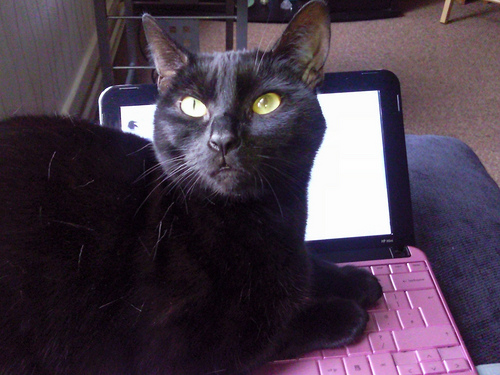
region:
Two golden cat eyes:
[181, 89, 281, 120]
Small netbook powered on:
[92, 68, 473, 374]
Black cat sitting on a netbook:
[0, 1, 382, 373]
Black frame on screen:
[95, 71, 418, 261]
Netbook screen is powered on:
[120, 90, 394, 237]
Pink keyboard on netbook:
[274, 246, 479, 373]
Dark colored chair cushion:
[401, 133, 498, 365]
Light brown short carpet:
[101, 1, 497, 186]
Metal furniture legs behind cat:
[92, 0, 249, 87]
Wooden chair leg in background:
[437, 0, 454, 25]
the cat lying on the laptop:
[1, 0, 383, 372]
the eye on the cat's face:
[251, 90, 281, 112]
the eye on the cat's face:
[178, 95, 208, 117]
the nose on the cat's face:
[209, 133, 236, 154]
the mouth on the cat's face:
[207, 153, 244, 176]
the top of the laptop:
[96, 67, 412, 243]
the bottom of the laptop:
[215, 243, 477, 373]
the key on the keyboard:
[391, 325, 459, 350]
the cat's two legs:
[267, 253, 382, 353]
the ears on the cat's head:
[142, 0, 331, 93]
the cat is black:
[47, 20, 364, 374]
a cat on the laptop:
[44, 42, 421, 370]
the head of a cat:
[176, 2, 336, 189]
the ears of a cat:
[135, 7, 352, 104]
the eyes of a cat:
[119, 79, 310, 127]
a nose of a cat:
[191, 115, 251, 166]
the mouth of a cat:
[199, 150, 281, 245]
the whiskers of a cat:
[150, 143, 293, 228]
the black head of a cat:
[113, 20, 362, 214]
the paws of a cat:
[320, 245, 402, 347]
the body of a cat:
[11, 36, 403, 316]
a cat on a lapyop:
[101, 40, 413, 362]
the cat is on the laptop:
[6, 79, 398, 368]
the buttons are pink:
[391, 278, 427, 374]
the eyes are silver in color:
[180, 89, 282, 121]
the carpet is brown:
[398, 35, 499, 99]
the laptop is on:
[112, 83, 467, 373]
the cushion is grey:
[414, 138, 499, 268]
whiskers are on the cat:
[67, 168, 140, 260]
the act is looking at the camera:
[23, 41, 362, 373]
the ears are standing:
[134, 9, 339, 74]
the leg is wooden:
[433, 2, 457, 24]